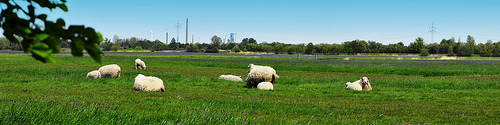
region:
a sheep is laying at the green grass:
[343, 75, 387, 112]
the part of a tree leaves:
[8, 3, 103, 78]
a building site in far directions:
[222, 26, 242, 48]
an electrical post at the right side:
[419, 15, 443, 45]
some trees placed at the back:
[245, 35, 403, 60]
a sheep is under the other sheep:
[244, 60, 279, 94]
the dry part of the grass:
[300, 68, 335, 78]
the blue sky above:
[300, 2, 370, 26]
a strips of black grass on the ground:
[43, 97, 118, 122]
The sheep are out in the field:
[40, 15, 430, 122]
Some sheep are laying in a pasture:
[61, 21, 446, 118]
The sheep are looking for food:
[63, 21, 435, 108]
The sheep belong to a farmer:
[73, 31, 416, 122]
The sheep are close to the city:
[41, 13, 451, 118]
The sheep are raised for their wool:
[56, 17, 402, 122]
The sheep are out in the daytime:
[58, 18, 449, 118]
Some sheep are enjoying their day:
[64, 17, 416, 122]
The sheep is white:
[124, 53, 149, 72]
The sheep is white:
[129, 70, 166, 97]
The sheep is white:
[98, 62, 123, 81]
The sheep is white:
[84, 63, 101, 85]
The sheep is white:
[216, 67, 243, 87]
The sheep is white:
[244, 59, 271, 73]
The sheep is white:
[246, 64, 279, 83]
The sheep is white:
[253, 78, 277, 95]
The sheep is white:
[339, 75, 376, 94]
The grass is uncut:
[2, 73, 499, 123]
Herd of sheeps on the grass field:
[83, 55, 373, 100]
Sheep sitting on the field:
[341, 75, 375, 93]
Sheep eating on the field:
[131, 57, 151, 71]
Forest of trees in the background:
[0, 34, 497, 54]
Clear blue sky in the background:
[0, 0, 497, 40]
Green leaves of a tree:
[0, 0, 109, 66]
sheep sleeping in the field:
[131, 72, 171, 94]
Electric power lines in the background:
[423, 20, 440, 42]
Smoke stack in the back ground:
[183, 17, 190, 42]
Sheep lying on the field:
[216, 72, 246, 83]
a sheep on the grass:
[133, 54, 147, 72]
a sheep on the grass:
[340, 72, 377, 95]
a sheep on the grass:
[130, 73, 165, 94]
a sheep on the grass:
[99, 63, 123, 80]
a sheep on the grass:
[84, 68, 101, 80]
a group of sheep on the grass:
[80, 50, 381, 104]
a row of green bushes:
[2, 30, 499, 60]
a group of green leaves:
[0, 0, 129, 80]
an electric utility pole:
[425, 20, 440, 47]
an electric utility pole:
[172, 17, 183, 44]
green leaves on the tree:
[12, 28, 35, 53]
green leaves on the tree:
[341, 30, 358, 45]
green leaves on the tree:
[451, 41, 460, 49]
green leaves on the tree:
[170, 38, 195, 55]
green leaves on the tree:
[148, 36, 173, 58]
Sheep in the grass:
[242, 57, 274, 99]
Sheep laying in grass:
[341, 74, 369, 94]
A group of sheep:
[211, 57, 288, 95]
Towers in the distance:
[169, 11, 197, 53]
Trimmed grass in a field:
[387, 83, 477, 124]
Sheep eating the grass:
[129, 55, 152, 74]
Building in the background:
[221, 24, 239, 49]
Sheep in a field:
[78, 52, 389, 114]